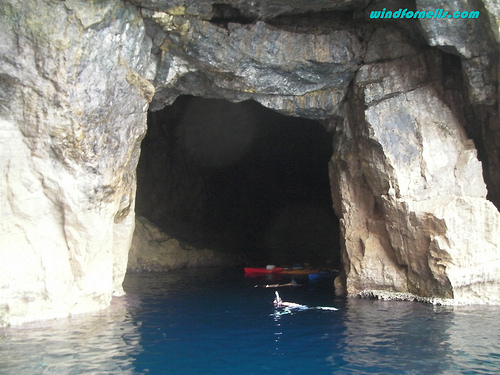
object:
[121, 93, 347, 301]
cave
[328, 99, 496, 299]
wall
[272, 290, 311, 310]
person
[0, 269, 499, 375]
water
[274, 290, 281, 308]
snorkel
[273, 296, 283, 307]
man's face